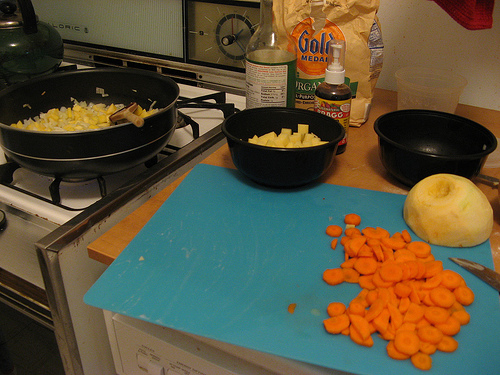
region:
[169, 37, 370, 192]
a bowl of cheese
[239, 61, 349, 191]
a black bowl of cheese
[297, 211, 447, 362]
a pile of orange food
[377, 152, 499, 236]
a large potato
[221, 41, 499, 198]
two black bowls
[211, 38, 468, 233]
black bowls on a counter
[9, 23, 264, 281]
a pot on a stove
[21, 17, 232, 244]
a pot on a gas stove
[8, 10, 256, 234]
an old gas stove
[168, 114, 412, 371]
a blue cutting mat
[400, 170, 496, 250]
half of a parsnip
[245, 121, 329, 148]
the other half of the parsnip cubed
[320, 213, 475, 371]
pile of sliced carrots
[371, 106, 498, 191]
small, black, shiney, cereal sized bowl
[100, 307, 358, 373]
upper corner of a dishwasher and its buttons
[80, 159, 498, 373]
thin, plastic, cutting pad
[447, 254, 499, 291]
tip of a medium sized knife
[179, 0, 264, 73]
dial timer on an old school stove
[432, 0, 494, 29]
corner of a cherry red dish towel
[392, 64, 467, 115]
clear container you get food in from the store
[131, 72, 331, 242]
the bowl is black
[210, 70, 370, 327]
the bowl is black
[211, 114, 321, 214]
the bowl is black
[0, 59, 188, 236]
Black pan on stove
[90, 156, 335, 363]
Blue cutting board on counter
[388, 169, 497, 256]
Half of potato on cutting board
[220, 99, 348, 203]
Bowl of diced potatoes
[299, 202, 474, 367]
Sliced carrots on cutting board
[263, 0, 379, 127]
Bag of flour on counter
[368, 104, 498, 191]
Empty black bowl on counter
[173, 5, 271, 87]
Timer on back of stove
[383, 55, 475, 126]
Clear plastic bowl on counter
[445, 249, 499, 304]
Knife on edge of cutting board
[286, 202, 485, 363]
Sliced carrots on the chopping board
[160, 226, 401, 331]
Blue chopping board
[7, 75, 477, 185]
Black cooking pots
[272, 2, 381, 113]
Flour packet on the countertop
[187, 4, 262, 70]
Timer on the stove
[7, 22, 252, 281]
Old and dated stove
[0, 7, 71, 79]
Green tea pot on the stove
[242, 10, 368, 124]
Ingredients for cooking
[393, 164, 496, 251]
Big white potato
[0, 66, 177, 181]
Food cooking on the stove top